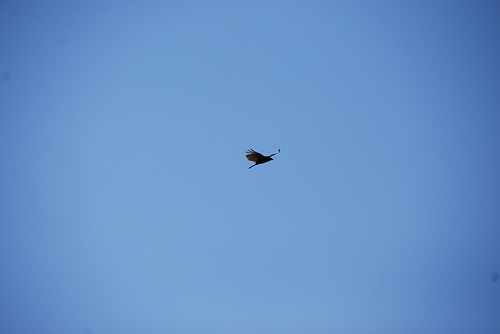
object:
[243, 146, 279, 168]
bird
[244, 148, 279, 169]
feathers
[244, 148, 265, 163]
wing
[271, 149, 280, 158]
wing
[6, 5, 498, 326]
sky